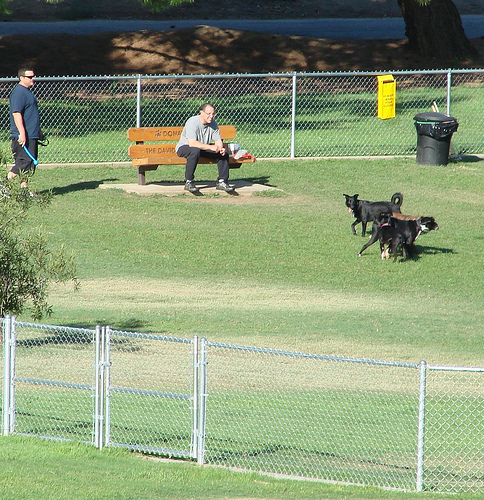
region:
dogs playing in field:
[341, 186, 444, 264]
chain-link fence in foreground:
[1, 311, 480, 498]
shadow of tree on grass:
[1, 312, 171, 356]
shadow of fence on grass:
[11, 406, 481, 497]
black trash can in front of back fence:
[413, 106, 460, 165]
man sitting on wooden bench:
[124, 101, 258, 197]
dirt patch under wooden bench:
[104, 175, 288, 199]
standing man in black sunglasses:
[7, 62, 54, 201]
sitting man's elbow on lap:
[166, 100, 250, 198]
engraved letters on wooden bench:
[139, 126, 179, 159]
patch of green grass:
[79, 193, 336, 283]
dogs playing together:
[320, 174, 482, 368]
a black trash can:
[401, 81, 481, 187]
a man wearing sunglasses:
[2, 50, 78, 205]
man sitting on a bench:
[127, 90, 288, 220]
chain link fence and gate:
[2, 309, 456, 496]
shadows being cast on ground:
[72, 2, 362, 71]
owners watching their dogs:
[8, 54, 451, 283]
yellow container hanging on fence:
[283, 65, 413, 159]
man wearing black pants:
[153, 93, 279, 206]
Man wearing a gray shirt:
[174, 96, 234, 196]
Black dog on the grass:
[333, 184, 402, 235]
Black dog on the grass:
[357, 214, 433, 259]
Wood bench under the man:
[114, 124, 249, 186]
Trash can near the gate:
[400, 101, 460, 169]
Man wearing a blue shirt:
[6, 67, 53, 202]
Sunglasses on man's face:
[18, 71, 35, 82]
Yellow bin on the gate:
[366, 58, 401, 128]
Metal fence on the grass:
[0, 308, 482, 499]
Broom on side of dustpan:
[423, 91, 470, 165]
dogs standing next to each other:
[345, 193, 439, 256]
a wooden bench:
[127, 125, 248, 179]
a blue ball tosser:
[22, 144, 38, 165]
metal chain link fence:
[0, 314, 483, 491]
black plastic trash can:
[411, 111, 458, 162]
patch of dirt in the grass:
[200, 196, 297, 203]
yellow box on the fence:
[376, 75, 396, 119]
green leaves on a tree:
[0, 141, 77, 318]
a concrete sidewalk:
[0, 18, 483, 38]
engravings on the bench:
[143, 129, 181, 153]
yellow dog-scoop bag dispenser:
[376, 73, 398, 120]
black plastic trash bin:
[412, 109, 459, 165]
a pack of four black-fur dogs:
[340, 190, 443, 264]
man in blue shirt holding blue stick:
[6, 66, 51, 204]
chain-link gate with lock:
[9, 318, 200, 465]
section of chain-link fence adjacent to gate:
[199, 333, 422, 493]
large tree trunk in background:
[389, 1, 474, 64]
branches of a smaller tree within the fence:
[0, 149, 91, 322]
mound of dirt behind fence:
[24, 29, 350, 71]